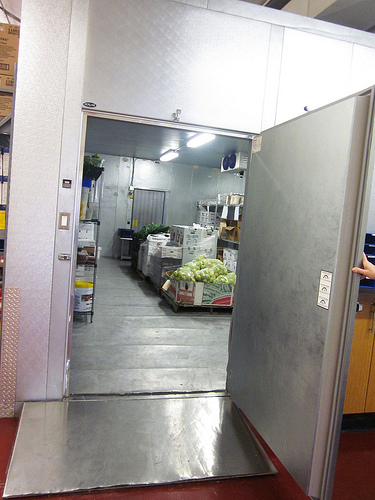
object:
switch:
[61, 215, 68, 226]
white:
[63, 217, 66, 224]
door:
[222, 82, 373, 499]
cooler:
[64, 111, 253, 397]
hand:
[351, 250, 375, 283]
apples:
[171, 255, 236, 285]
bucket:
[74, 279, 95, 314]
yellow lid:
[75, 282, 92, 288]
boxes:
[170, 222, 219, 262]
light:
[159, 133, 217, 162]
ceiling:
[83, 116, 251, 169]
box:
[165, 270, 236, 306]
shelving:
[75, 217, 100, 323]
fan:
[220, 152, 247, 173]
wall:
[101, 156, 244, 226]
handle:
[355, 300, 364, 314]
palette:
[160, 290, 240, 314]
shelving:
[195, 191, 244, 262]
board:
[0, 393, 280, 500]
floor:
[70, 323, 225, 392]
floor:
[333, 417, 375, 499]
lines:
[94, 305, 189, 390]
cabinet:
[358, 232, 375, 290]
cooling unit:
[0, 0, 373, 421]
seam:
[75, 338, 223, 354]